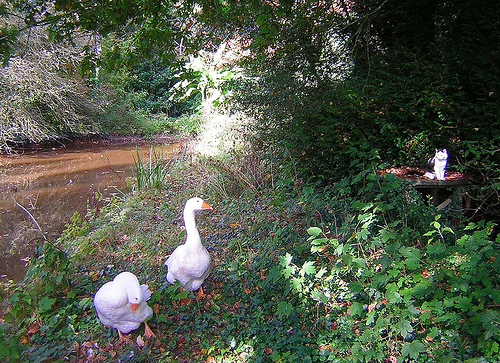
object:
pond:
[0, 164, 98, 337]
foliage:
[483, 341, 499, 359]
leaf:
[36, 294, 58, 313]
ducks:
[93, 271, 156, 342]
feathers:
[168, 245, 187, 263]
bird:
[164, 197, 213, 299]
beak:
[201, 201, 214, 210]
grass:
[127, 140, 178, 188]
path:
[413, 157, 468, 196]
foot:
[138, 322, 155, 341]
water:
[67, 142, 135, 215]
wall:
[169, 86, 244, 159]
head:
[187, 196, 213, 213]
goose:
[170, 197, 202, 299]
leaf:
[378, 224, 403, 244]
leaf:
[401, 241, 421, 268]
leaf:
[383, 267, 408, 283]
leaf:
[381, 284, 411, 311]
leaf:
[431, 264, 458, 287]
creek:
[0, 133, 169, 235]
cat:
[424, 147, 449, 181]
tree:
[0, 0, 500, 195]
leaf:
[272, 301, 294, 317]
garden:
[0, 117, 498, 358]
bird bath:
[411, 167, 467, 206]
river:
[51, 134, 183, 182]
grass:
[378, 285, 497, 358]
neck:
[183, 206, 203, 246]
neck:
[112, 270, 141, 297]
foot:
[196, 287, 205, 297]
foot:
[116, 328, 133, 344]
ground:
[0, 130, 498, 359]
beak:
[130, 303, 139, 313]